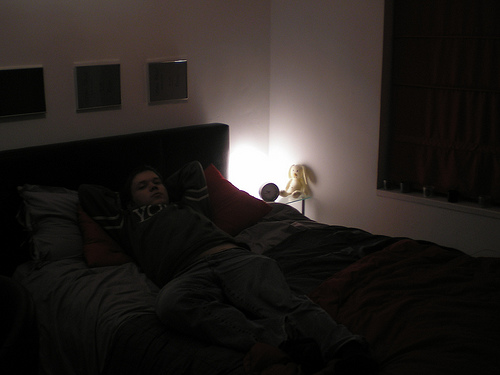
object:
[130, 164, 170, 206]
soccer ball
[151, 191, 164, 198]
mouth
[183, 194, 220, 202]
stripe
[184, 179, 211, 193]
stripe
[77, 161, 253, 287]
shirt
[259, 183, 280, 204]
clock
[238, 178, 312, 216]
nightstand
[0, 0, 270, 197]
wall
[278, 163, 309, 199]
stuffed rabbit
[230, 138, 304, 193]
light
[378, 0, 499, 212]
window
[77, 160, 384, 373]
boy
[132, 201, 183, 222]
white letters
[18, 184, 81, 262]
pillow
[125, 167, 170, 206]
head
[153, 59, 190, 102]
frame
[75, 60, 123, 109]
frame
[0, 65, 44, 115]
frame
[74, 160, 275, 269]
pillow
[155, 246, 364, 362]
sweatpants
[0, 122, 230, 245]
headboard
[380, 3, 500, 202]
curtain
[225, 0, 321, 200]
corner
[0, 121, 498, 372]
bed